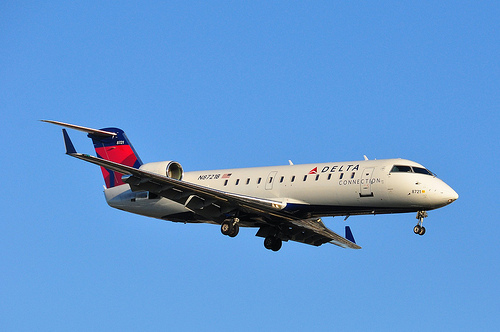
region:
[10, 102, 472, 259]
Airplane flying in sky.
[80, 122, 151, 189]
Red and blue tail of airplane.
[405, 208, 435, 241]
Landing gear of plane.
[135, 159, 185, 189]
Engine of delta plane.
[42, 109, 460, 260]
White delta airplane.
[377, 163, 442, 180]
Pilot windows of airline.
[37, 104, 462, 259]
Descending delta airplane.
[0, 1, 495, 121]
Clear blue bright sky.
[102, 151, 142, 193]
Shadow on tail of plane.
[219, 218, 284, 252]
Wheels on delta plane.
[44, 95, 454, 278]
a plane in the sky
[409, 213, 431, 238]
front wheels of a plane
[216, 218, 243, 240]
right wheel of a plane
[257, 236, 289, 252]
left wheel of a plane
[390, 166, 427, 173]
front windows on a plane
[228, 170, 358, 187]
a row of windows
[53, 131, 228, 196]
the wing of a plane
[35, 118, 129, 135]
a tail wing of a plane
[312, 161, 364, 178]
a name on a plane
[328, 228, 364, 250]
the left wing tip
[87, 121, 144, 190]
the airplane tail is red and blue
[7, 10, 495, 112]
the blue sky is clear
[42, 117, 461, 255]
the airplane is flying for DELTA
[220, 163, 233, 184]
a United States flag is on the side of the airplane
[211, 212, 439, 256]
the airplane wheels are down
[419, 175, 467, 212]
the nose of the airplane is pointed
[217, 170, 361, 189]
the airplane has lots of small windows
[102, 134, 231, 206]
the airplane wing has a light on it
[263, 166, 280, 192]
an emergency exit on the airplane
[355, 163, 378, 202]
the airplane passenger door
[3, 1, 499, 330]
A plane in the sky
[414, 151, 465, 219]
Nose of the plane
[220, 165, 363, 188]
Windows on side of a plane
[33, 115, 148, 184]
Tail of the plane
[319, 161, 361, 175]
The word "DELTA" on plane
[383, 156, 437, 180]
Windows on front of the plane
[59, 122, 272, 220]
Wing of a plane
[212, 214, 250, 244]
Two black round wheels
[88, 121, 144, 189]
The tail is blue and red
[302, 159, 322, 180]
Red symbol on a plane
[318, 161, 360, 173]
blue Delta name on white plane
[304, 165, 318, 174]
orange delta logo on white plane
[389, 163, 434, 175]
window in pilot's cockpit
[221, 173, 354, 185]
passenger windows on side of plane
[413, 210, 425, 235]
landing gear on plane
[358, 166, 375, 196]
door on side of plane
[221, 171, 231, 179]
american flag on side of plane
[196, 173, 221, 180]
identification number on plane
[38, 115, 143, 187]
tail of Delta plane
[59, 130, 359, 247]
wings on Delta plane